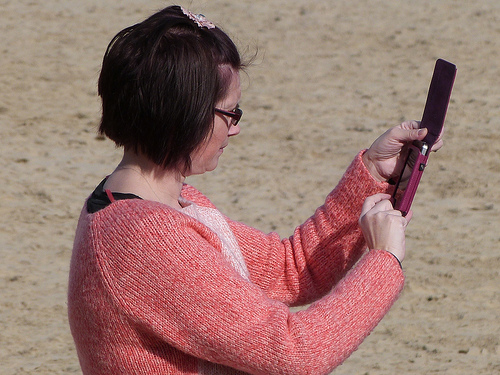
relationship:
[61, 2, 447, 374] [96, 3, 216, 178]
lady with hair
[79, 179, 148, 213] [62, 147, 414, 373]
black shirt under sweater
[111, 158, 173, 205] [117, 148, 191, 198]
necklace on womans neck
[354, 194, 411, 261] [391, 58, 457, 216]
hand pushing buttons on cell phone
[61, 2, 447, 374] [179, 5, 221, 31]
lady have bow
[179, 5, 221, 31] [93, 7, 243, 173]
bow in head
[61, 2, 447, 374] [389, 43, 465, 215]
lady holding cellphone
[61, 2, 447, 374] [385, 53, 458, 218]
lady texting on cell phone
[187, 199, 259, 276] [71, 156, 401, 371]
shirt under sweater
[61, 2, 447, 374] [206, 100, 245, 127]
lady wearing eye glasses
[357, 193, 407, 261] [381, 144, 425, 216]
hand on bottom of system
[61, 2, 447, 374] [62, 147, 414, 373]
lady wearing sweater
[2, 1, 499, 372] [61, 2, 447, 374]
sand behind lady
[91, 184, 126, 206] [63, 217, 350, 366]
shirt under sweater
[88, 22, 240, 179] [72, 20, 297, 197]
hair on top of head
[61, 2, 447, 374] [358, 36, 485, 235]
lady holding phone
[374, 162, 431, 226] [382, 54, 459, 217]
case on phone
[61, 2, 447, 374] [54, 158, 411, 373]
lady wearing red sweater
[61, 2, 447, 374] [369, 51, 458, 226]
lady looking at phone